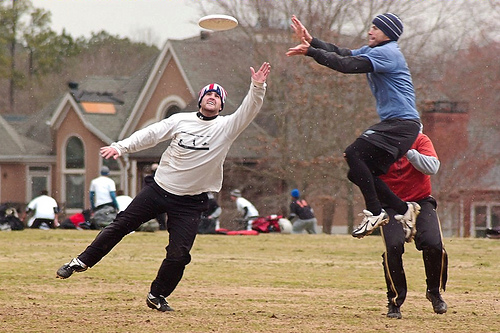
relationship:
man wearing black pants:
[55, 61, 273, 312] [94, 242, 181, 311]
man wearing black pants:
[55, 61, 273, 312] [62, 175, 212, 332]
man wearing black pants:
[55, 61, 273, 312] [85, 274, 215, 304]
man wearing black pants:
[55, 61, 273, 312] [62, 186, 232, 331]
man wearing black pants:
[155, 170, 191, 250] [110, 211, 192, 313]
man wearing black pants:
[55, 61, 273, 312] [99, 187, 183, 285]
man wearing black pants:
[55, 61, 273, 312] [88, 235, 202, 318]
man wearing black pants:
[55, 61, 273, 312] [103, 226, 186, 285]